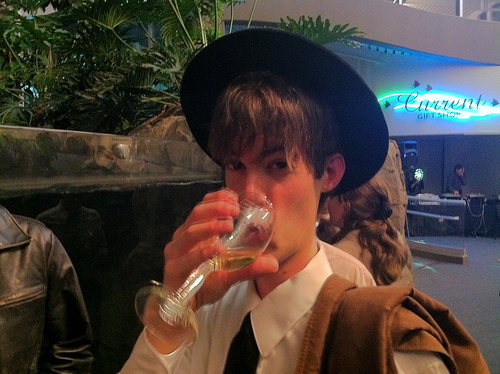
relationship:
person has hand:
[109, 28, 396, 373] [141, 185, 278, 329]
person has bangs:
[109, 28, 396, 373] [205, 116, 310, 175]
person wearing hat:
[109, 28, 396, 373] [167, 27, 392, 201]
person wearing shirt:
[109, 28, 396, 373] [102, 241, 334, 374]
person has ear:
[109, 28, 396, 373] [316, 150, 350, 196]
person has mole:
[109, 28, 396, 373] [281, 268, 290, 276]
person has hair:
[109, 28, 396, 373] [204, 68, 347, 176]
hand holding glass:
[141, 185, 278, 329] [125, 188, 276, 350]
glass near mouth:
[125, 188, 276, 350] [240, 222, 276, 249]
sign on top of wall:
[372, 76, 499, 129] [358, 64, 500, 141]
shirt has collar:
[102, 241, 334, 374] [212, 238, 334, 360]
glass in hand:
[125, 188, 276, 350] [141, 185, 278, 329]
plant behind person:
[268, 11, 371, 52] [109, 28, 396, 373]